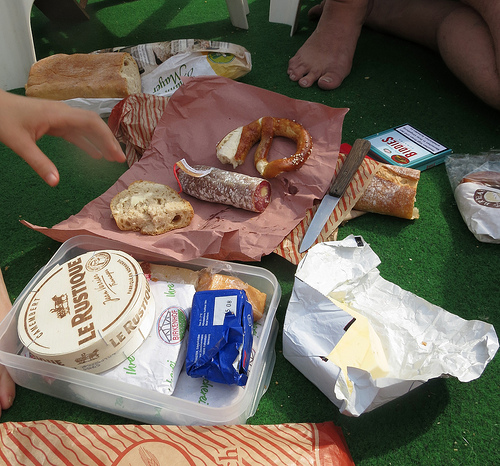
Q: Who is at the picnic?
A: The people.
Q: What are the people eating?
A: Cheese.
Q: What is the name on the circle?
A: Le Rustique.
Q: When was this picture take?
A: During the day.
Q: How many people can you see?
A: Two.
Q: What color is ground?
A: Green.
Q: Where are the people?
A: On the ground.